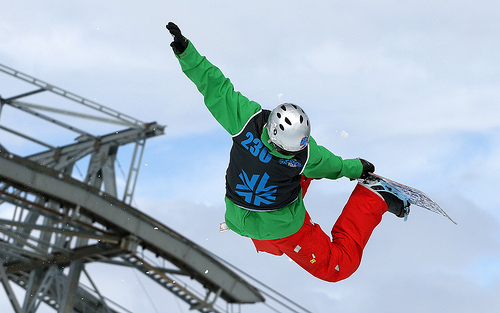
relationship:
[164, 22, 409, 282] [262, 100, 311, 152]
man wearing helmet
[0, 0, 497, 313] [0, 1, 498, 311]
cloud in sky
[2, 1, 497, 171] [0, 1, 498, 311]
cloud in sky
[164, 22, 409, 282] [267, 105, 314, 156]
man has head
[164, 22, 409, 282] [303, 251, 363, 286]
man has knee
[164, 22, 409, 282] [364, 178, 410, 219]
man wearing boot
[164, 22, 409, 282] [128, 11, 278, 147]
man has arm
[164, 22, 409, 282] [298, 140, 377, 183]
man has arm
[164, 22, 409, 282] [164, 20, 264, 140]
man has arm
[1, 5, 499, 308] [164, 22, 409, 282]
cloudy sky above man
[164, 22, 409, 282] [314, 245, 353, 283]
man has knee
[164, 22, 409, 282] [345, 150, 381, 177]
man has hand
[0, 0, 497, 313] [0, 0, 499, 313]
cloud in cloudy sky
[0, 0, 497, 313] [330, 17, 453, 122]
cloud in sky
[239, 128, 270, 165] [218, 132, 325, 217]
number on vest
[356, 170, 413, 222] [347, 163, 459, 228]
boot on snowboard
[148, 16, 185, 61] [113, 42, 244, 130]
glove on arm